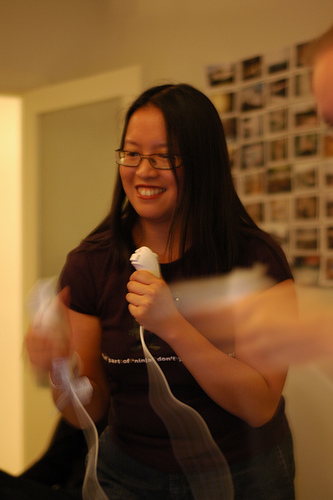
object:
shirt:
[56, 215, 295, 475]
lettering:
[101, 351, 182, 363]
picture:
[242, 55, 262, 81]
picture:
[239, 80, 264, 113]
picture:
[268, 107, 289, 132]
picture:
[241, 113, 261, 137]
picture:
[269, 133, 288, 161]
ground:
[300, 103, 308, 128]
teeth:
[138, 187, 165, 196]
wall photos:
[199, 34, 332, 293]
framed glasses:
[114, 147, 184, 170]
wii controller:
[29, 277, 108, 500]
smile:
[134, 183, 168, 198]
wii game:
[131, 245, 163, 341]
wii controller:
[129, 246, 236, 500]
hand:
[126, 270, 173, 327]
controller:
[130, 246, 161, 278]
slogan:
[100, 355, 179, 366]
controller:
[30, 278, 69, 339]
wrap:
[48, 353, 81, 390]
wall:
[149, 0, 322, 64]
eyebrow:
[154, 142, 177, 149]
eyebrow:
[123, 139, 142, 147]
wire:
[138, 329, 236, 500]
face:
[114, 97, 184, 218]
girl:
[24, 82, 298, 496]